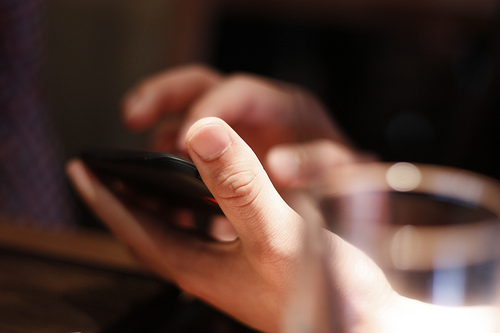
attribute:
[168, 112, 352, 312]
finger — middle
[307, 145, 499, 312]
glass — clear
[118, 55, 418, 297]
hand — blurry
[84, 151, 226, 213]
phone — black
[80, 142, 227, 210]
phone — flat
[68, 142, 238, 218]
cell phone — black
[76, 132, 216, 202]
cellphone — black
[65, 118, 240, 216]
phone — black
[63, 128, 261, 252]
cell phone — black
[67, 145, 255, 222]
phone — black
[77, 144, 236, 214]
cell phone — black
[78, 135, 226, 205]
cellphone — black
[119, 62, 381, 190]
hand — blurry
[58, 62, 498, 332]
person — white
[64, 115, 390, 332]
hand — blurry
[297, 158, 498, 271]
cup edge — round, shiny